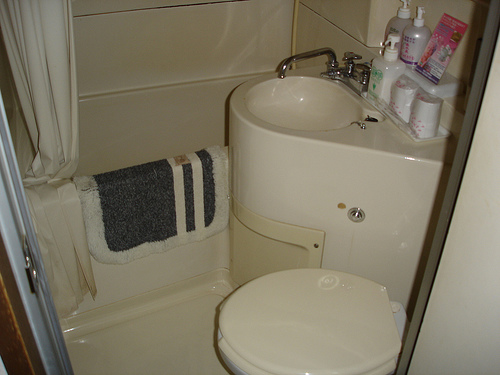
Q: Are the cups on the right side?
A: Yes, the cups are on the right of the image.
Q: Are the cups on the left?
A: No, the cups are on the right of the image.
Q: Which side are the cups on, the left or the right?
A: The cups are on the right of the image.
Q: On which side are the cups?
A: The cups are on the right of the image.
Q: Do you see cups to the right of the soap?
A: Yes, there are cups to the right of the soap.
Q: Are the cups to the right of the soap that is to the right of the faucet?
A: Yes, the cups are to the right of the soap.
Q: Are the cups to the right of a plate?
A: No, the cups are to the right of the soap.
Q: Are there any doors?
A: Yes, there is a door.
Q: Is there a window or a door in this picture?
A: Yes, there is a door.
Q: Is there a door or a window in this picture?
A: Yes, there is a door.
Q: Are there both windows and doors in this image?
A: No, there is a door but no windows.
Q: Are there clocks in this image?
A: No, there are no clocks.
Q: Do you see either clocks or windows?
A: No, there are no clocks or windows.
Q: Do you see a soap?
A: Yes, there is a soap.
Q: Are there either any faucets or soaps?
A: Yes, there is a soap.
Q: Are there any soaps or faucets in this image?
A: Yes, there is a soap.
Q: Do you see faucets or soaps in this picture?
A: Yes, there is a soap.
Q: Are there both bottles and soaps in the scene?
A: Yes, there are both a soap and a bottle.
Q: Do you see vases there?
A: No, there are no vases.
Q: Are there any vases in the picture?
A: No, there are no vases.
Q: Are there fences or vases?
A: No, there are no vases or fences.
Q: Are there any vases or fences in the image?
A: No, there are no vases or fences.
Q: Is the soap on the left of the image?
A: No, the soap is on the right of the image.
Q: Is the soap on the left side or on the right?
A: The soap is on the right of the image.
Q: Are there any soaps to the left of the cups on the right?
A: Yes, there is a soap to the left of the cups.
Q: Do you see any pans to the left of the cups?
A: No, there is a soap to the left of the cups.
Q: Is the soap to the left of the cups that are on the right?
A: Yes, the soap is to the left of the cups.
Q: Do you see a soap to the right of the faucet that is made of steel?
A: Yes, there is a soap to the right of the tap.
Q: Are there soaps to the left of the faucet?
A: No, the soap is to the right of the faucet.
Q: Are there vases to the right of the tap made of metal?
A: No, there is a soap to the right of the faucet.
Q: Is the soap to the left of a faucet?
A: No, the soap is to the right of a faucet.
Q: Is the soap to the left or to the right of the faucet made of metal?
A: The soap is to the right of the faucet.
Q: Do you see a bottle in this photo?
A: Yes, there is a bottle.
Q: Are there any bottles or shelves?
A: Yes, there is a bottle.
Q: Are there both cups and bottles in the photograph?
A: Yes, there are both a bottle and a cup.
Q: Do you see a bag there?
A: No, there are no bags.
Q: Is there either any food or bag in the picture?
A: No, there are no bags or food.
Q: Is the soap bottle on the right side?
A: Yes, the bottle is on the right of the image.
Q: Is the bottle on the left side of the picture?
A: No, the bottle is on the right of the image.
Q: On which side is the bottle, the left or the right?
A: The bottle is on the right of the image.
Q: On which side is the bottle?
A: The bottle is on the right of the image.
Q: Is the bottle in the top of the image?
A: Yes, the bottle is in the top of the image.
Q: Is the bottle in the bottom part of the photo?
A: No, the bottle is in the top of the image.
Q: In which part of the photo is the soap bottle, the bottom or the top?
A: The bottle is in the top of the image.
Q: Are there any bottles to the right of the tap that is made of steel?
A: Yes, there is a bottle to the right of the faucet.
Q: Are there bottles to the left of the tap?
A: No, the bottle is to the right of the tap.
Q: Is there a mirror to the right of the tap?
A: No, there is a bottle to the right of the tap.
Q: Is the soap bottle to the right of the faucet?
A: Yes, the bottle is to the right of the faucet.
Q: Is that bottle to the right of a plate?
A: No, the bottle is to the right of the faucet.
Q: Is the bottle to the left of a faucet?
A: No, the bottle is to the right of a faucet.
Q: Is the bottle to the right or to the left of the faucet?
A: The bottle is to the right of the faucet.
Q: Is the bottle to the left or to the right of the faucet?
A: The bottle is to the right of the faucet.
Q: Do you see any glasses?
A: No, there are no glasses.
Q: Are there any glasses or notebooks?
A: No, there are no glasses or notebooks.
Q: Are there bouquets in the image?
A: No, there are no bouquets.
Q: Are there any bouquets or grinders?
A: No, there are no bouquets or grinders.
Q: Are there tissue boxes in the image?
A: No, there are no tissue boxes.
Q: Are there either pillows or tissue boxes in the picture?
A: No, there are no tissue boxes or pillows.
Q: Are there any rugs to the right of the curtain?
A: Yes, there is a rug to the right of the curtain.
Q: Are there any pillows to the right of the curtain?
A: No, there is a rug to the right of the curtain.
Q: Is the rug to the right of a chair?
A: No, the rug is to the right of the curtain.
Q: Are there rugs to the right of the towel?
A: Yes, there is a rug to the right of the towel.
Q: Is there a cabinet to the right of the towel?
A: No, there is a rug to the right of the towel.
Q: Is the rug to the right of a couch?
A: No, the rug is to the right of a towel.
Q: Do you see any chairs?
A: No, there are no chairs.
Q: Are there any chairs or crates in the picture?
A: No, there are no chairs or crates.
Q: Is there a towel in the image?
A: Yes, there is a towel.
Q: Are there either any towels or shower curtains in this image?
A: Yes, there is a towel.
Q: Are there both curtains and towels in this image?
A: Yes, there are both a towel and a curtain.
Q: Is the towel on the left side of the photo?
A: Yes, the towel is on the left of the image.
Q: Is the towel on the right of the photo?
A: No, the towel is on the left of the image.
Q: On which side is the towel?
A: The towel is on the left of the image.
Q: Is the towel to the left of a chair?
A: No, the towel is to the left of the rug.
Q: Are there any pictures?
A: No, there are no pictures.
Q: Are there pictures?
A: No, there are no pictures.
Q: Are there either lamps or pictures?
A: No, there are no pictures or lamps.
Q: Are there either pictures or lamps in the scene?
A: No, there are no pictures or lamps.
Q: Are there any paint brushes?
A: No, there are no paint brushes.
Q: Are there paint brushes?
A: No, there are no paint brushes.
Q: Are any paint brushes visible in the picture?
A: No, there are no paint brushes.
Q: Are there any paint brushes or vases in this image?
A: No, there are no paint brushes or vases.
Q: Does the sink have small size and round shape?
A: Yes, the sink is small and round.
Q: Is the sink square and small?
A: No, the sink is small but round.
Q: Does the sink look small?
A: Yes, the sink is small.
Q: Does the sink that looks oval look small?
A: Yes, the sink is small.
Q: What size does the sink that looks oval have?
A: The sink has small size.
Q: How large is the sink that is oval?
A: The sink is small.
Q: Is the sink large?
A: No, the sink is small.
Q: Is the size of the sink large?
A: No, the sink is small.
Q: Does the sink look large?
A: No, the sink is small.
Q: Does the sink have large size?
A: No, the sink is small.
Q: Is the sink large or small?
A: The sink is small.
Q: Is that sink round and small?
A: Yes, the sink is round and small.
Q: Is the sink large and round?
A: No, the sink is round but small.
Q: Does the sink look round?
A: Yes, the sink is round.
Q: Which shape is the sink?
A: The sink is round.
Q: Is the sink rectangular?
A: No, the sink is round.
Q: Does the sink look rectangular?
A: No, the sink is round.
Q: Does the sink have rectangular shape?
A: No, the sink is round.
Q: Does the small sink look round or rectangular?
A: The sink is round.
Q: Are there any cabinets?
A: No, there are no cabinets.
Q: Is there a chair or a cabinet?
A: No, there are no cabinets or chairs.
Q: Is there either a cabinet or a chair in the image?
A: No, there are no cabinets or chairs.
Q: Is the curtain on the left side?
A: Yes, the curtain is on the left of the image.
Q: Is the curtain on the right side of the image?
A: No, the curtain is on the left of the image.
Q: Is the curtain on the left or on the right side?
A: The curtain is on the left of the image.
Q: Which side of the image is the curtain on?
A: The curtain is on the left of the image.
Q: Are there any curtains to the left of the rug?
A: Yes, there is a curtain to the left of the rug.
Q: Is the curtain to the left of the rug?
A: Yes, the curtain is to the left of the rug.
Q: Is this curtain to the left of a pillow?
A: No, the curtain is to the left of the rug.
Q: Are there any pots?
A: No, there are no pots.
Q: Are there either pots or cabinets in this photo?
A: No, there are no pots or cabinets.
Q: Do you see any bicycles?
A: No, there are no bicycles.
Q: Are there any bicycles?
A: No, there are no bicycles.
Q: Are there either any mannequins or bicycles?
A: No, there are no bicycles or mannequins.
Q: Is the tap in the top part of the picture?
A: Yes, the tap is in the top of the image.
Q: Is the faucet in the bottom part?
A: No, the faucet is in the top of the image.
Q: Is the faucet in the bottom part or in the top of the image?
A: The faucet is in the top of the image.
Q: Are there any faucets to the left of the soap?
A: Yes, there is a faucet to the left of the soap.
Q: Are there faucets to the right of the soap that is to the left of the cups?
A: No, the faucet is to the left of the soap.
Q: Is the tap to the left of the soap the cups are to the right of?
A: Yes, the tap is to the left of the soap.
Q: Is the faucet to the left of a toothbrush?
A: No, the faucet is to the left of the soap.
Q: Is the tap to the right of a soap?
A: No, the tap is to the left of a soap.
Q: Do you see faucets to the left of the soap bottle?
A: Yes, there is a faucet to the left of the bottle.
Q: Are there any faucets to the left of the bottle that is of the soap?
A: Yes, there is a faucet to the left of the bottle.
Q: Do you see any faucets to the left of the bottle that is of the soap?
A: Yes, there is a faucet to the left of the bottle.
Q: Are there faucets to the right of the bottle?
A: No, the faucet is to the left of the bottle.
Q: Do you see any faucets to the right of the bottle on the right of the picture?
A: No, the faucet is to the left of the bottle.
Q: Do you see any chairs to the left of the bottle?
A: No, there is a faucet to the left of the bottle.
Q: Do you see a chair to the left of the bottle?
A: No, there is a faucet to the left of the bottle.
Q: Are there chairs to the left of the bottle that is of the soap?
A: No, there is a faucet to the left of the bottle.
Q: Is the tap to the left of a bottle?
A: Yes, the tap is to the left of a bottle.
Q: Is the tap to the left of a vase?
A: No, the tap is to the left of a bottle.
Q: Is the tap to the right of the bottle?
A: No, the tap is to the left of the bottle.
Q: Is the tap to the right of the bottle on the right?
A: No, the tap is to the left of the bottle.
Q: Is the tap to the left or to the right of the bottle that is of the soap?
A: The tap is to the left of the bottle.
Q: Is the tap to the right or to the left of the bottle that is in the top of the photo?
A: The tap is to the left of the bottle.